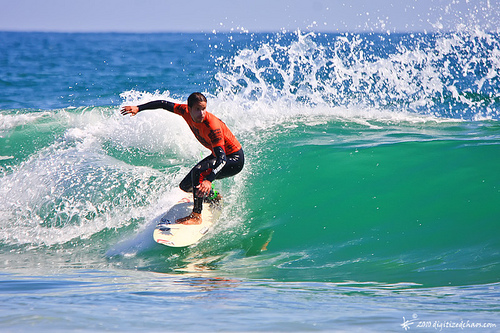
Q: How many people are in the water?
A: One.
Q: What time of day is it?
A: Daytime.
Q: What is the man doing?
A: Surfing.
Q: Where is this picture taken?
A: The Ocean.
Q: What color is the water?
A: Blue and green.